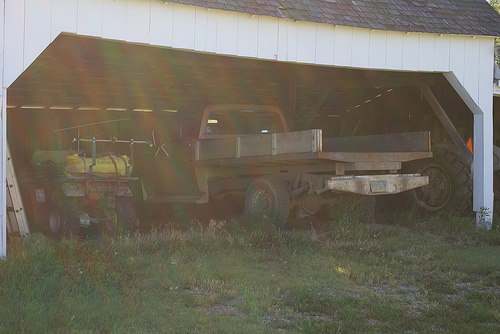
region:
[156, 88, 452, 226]
truck parked under a carport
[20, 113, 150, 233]
cart parked under a carport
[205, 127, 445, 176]
flatbed of the truck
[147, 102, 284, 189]
cab of the truck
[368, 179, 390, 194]
license plate on the truck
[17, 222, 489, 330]
grass in front of the carport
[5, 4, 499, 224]
white carport with black roof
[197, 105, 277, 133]
back window of the truck cab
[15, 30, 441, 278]
beams of sunlight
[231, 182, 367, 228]
tires on the truck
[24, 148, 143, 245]
an all terrain vehicle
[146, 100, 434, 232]
an old pickup truck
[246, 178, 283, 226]
a wheel on a vehicle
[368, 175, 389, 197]
a license plate on a rusty bumper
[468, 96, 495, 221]
a white wooden post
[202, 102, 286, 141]
the rear window of a pickup truck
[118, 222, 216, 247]
tall blades of brown grass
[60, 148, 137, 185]
a yellow container on a cargo rack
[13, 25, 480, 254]
vehicles parked in a building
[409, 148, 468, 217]
the big wheel of a tractor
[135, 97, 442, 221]
A truck in the barn.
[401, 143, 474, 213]
A tractor tire in the barn.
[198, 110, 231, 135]
Sticker in the window.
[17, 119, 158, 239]
Tractor in the barn.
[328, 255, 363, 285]
Yellow patch on the ground.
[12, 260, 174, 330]
The grass is green.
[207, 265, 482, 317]
Gravel in the grass.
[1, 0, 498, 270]
The barn is white.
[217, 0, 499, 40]
The roof is black.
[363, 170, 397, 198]
License plate on the back of the truck.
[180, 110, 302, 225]
this is a garage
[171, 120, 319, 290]
this is a truck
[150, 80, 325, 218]
the truck is old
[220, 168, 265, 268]
this is a tire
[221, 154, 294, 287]
the tire is old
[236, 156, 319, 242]
the tire is round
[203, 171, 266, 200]
the tire is dirty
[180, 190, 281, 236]
the tire is black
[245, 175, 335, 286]
the tire is rubber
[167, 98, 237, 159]
this is a window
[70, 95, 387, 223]
red truck in barn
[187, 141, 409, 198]
brown bed on truck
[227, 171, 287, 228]
black tire on truck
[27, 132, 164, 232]
green and yellow farm tool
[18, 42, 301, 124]
brown planks on ceiling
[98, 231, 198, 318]
green grass outside barn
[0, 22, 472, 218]
white frame on barn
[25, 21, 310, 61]
wooden frame on barn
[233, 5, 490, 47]
grey roof on barn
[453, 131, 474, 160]
orange triangle beside truck